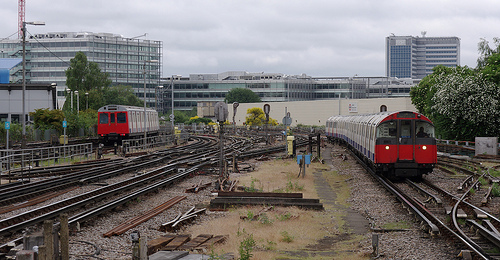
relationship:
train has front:
[95, 103, 161, 137] [95, 105, 128, 138]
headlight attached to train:
[385, 143, 392, 151] [324, 111, 440, 179]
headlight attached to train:
[423, 144, 428, 150] [324, 111, 440, 179]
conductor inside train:
[417, 124, 430, 136] [324, 111, 440, 179]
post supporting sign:
[299, 155, 307, 179] [296, 152, 313, 162]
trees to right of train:
[410, 37, 500, 144] [324, 111, 440, 179]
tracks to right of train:
[0, 123, 313, 259] [95, 103, 161, 137]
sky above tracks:
[0, 2, 500, 77] [0, 123, 313, 259]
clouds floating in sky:
[1, 2, 499, 76] [0, 2, 500, 77]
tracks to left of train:
[0, 123, 313, 259] [324, 111, 440, 179]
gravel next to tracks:
[64, 166, 221, 259] [0, 123, 313, 259]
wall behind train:
[228, 96, 424, 128] [324, 111, 440, 179]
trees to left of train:
[59, 50, 140, 110] [95, 103, 161, 137]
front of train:
[374, 111, 439, 179] [324, 111, 440, 179]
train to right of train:
[324, 111, 440, 179] [95, 103, 161, 137]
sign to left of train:
[296, 152, 313, 162] [324, 111, 440, 179]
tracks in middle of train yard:
[0, 123, 313, 259] [1, 120, 499, 259]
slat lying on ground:
[103, 193, 186, 238] [0, 126, 500, 259]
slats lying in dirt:
[210, 189, 322, 206] [169, 146, 377, 259]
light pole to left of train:
[22, 20, 48, 134] [95, 103, 161, 137]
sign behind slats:
[296, 152, 313, 162] [210, 189, 322, 206]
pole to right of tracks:
[285, 135, 296, 156] [0, 123, 313, 259]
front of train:
[95, 105, 128, 138] [95, 103, 161, 137]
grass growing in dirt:
[238, 236, 256, 259] [169, 146, 377, 259]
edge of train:
[131, 108, 160, 135] [95, 103, 161, 137]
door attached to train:
[396, 118, 413, 160] [324, 111, 440, 179]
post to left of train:
[299, 155, 307, 179] [324, 111, 440, 179]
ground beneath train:
[0, 126, 500, 259] [95, 103, 161, 137]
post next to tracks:
[169, 73, 180, 130] [0, 123, 313, 259]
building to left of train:
[0, 32, 162, 108] [95, 103, 161, 137]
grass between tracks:
[487, 167, 500, 182] [355, 154, 500, 259]